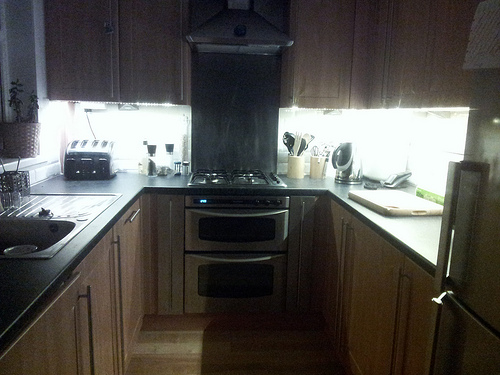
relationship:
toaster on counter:
[58, 131, 126, 186] [50, 149, 375, 198]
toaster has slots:
[58, 131, 126, 186] [99, 137, 104, 151]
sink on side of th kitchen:
[4, 204, 76, 254] [8, 21, 472, 364]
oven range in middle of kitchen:
[189, 165, 297, 267] [8, 21, 472, 364]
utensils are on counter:
[281, 127, 331, 181] [50, 149, 375, 198]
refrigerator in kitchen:
[420, 93, 485, 363] [8, 21, 472, 364]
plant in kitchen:
[4, 72, 50, 152] [8, 21, 472, 364]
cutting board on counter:
[345, 171, 450, 222] [322, 153, 479, 259]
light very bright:
[293, 97, 474, 123] [344, 106, 378, 119]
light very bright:
[52, 93, 188, 117] [344, 106, 378, 119]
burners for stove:
[197, 172, 226, 185] [191, 158, 291, 191]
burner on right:
[233, 172, 267, 186] [233, 159, 269, 194]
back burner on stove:
[190, 160, 267, 176] [191, 158, 291, 191]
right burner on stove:
[230, 158, 266, 175] [191, 158, 291, 191]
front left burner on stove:
[189, 174, 228, 186] [191, 158, 291, 191]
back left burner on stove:
[192, 161, 226, 174] [191, 158, 291, 191]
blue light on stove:
[232, 21, 255, 38] [191, 158, 291, 191]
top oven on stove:
[184, 205, 293, 250] [191, 158, 291, 191]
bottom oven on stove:
[172, 250, 291, 312] [191, 158, 291, 191]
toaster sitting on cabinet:
[58, 131, 126, 186] [55, 135, 300, 188]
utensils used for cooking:
[281, 127, 331, 181] [206, 122, 305, 198]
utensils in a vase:
[281, 127, 331, 181] [286, 153, 312, 180]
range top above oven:
[191, 158, 291, 191] [176, 190, 305, 319]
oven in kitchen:
[176, 190, 305, 319] [8, 21, 472, 364]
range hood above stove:
[176, 8, 308, 74] [191, 158, 291, 191]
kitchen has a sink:
[8, 21, 472, 364] [4, 204, 76, 254]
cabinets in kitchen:
[42, 1, 499, 79] [8, 21, 472, 364]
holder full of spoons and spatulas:
[313, 155, 330, 180] [284, 134, 340, 157]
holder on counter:
[313, 155, 330, 180] [50, 149, 375, 198]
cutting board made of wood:
[345, 171, 450, 222] [387, 192, 404, 205]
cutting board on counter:
[345, 171, 450, 222] [50, 149, 375, 198]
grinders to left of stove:
[145, 135, 179, 179] [191, 158, 291, 191]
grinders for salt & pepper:
[145, 135, 179, 179] [143, 140, 178, 179]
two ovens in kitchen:
[176, 190, 305, 319] [8, 21, 472, 364]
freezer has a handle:
[449, 107, 492, 306] [436, 149, 451, 294]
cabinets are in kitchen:
[42, 1, 499, 79] [8, 21, 472, 364]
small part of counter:
[48, 170, 120, 195] [50, 149, 375, 198]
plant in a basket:
[4, 72, 50, 152] [9, 119, 40, 151]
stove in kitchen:
[191, 158, 291, 191] [8, 21, 472, 364]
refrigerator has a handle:
[420, 93, 485, 363] [411, 291, 450, 371]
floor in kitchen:
[129, 312, 329, 370] [8, 21, 472, 364]